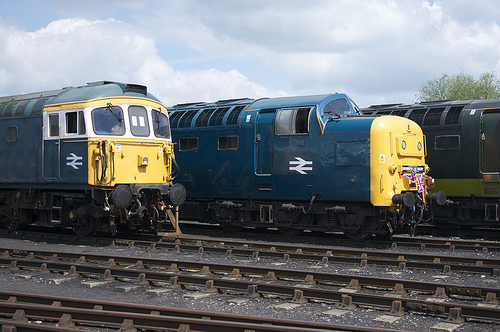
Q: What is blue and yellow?
A: Train.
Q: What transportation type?
A: Train.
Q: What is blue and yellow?
A: Train.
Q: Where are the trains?
A: Station.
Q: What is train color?
A: Blue.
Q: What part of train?
A: Front.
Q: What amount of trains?
A: Three.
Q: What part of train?
A: Engine.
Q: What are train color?
A: Blue.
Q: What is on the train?
A: Windows.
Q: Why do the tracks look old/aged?
A: They're rusty.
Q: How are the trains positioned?
A: Next to each other.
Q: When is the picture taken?
A: Daytime.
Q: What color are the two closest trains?
A: Blue and yellow.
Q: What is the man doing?
A: There is no man.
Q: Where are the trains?
A: On the train tracks.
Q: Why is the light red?
A: There is no light.